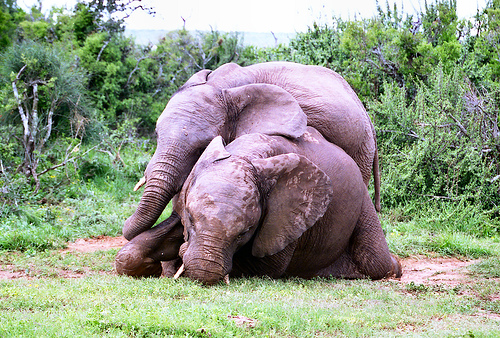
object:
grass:
[63, 270, 493, 338]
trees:
[382, 19, 499, 158]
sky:
[194, 1, 316, 26]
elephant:
[112, 126, 401, 285]